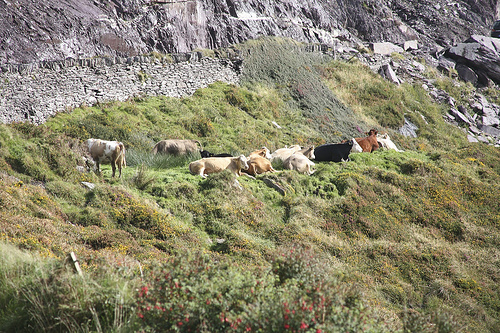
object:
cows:
[314, 138, 361, 164]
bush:
[177, 98, 242, 132]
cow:
[189, 153, 253, 177]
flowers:
[111, 197, 129, 209]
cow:
[286, 145, 321, 177]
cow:
[377, 132, 405, 154]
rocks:
[445, 30, 500, 81]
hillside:
[0, 0, 247, 122]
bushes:
[102, 237, 172, 265]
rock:
[367, 39, 406, 57]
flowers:
[133, 283, 153, 297]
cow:
[312, 138, 364, 164]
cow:
[342, 129, 380, 152]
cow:
[79, 138, 126, 178]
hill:
[0, 0, 499, 332]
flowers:
[425, 190, 454, 210]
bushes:
[381, 275, 481, 320]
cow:
[151, 137, 203, 157]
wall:
[0, 48, 237, 127]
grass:
[0, 62, 497, 332]